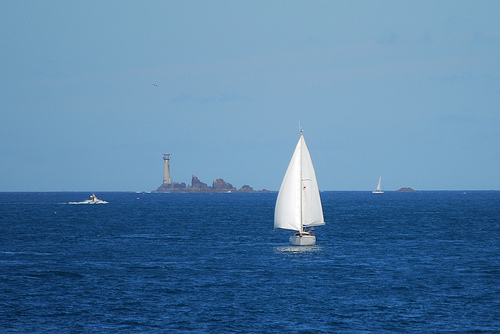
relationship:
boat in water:
[271, 124, 326, 246] [4, 187, 498, 330]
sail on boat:
[272, 126, 326, 230] [271, 124, 326, 246]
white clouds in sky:
[99, 53, 129, 104] [5, 4, 493, 127]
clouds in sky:
[190, 15, 386, 86] [2, 3, 499, 193]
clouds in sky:
[190, 15, 386, 86] [22, 25, 114, 120]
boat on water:
[271, 124, 326, 253] [107, 219, 209, 332]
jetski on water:
[82, 191, 99, 204] [4, 187, 498, 330]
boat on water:
[271, 124, 326, 246] [4, 187, 498, 330]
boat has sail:
[271, 124, 326, 246] [301, 133, 326, 230]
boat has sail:
[271, 124, 326, 246] [272, 134, 300, 230]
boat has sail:
[271, 124, 326, 246] [272, 125, 325, 231]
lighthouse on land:
[120, 132, 215, 222] [180, 157, 265, 197]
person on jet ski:
[85, 190, 95, 201] [77, 200, 112, 205]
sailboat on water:
[370, 175, 387, 195] [4, 187, 498, 330]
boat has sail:
[271, 124, 326, 246] [302, 116, 326, 226]